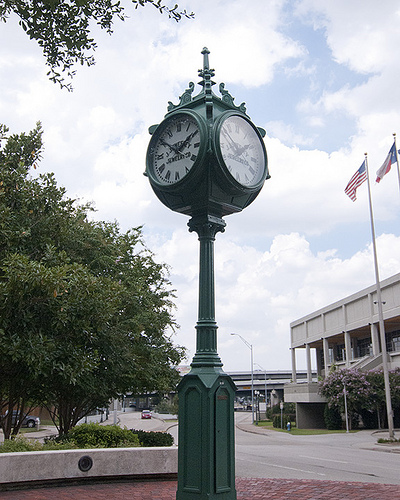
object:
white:
[170, 161, 183, 170]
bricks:
[2, 474, 396, 500]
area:
[0, 271, 398, 498]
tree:
[316, 361, 400, 431]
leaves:
[316, 363, 374, 413]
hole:
[78, 454, 95, 476]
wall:
[0, 451, 177, 487]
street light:
[228, 332, 255, 425]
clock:
[146, 108, 269, 194]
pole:
[175, 215, 239, 500]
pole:
[392, 132, 400, 186]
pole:
[363, 150, 397, 439]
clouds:
[0, 3, 399, 371]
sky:
[0, 7, 397, 369]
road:
[18, 394, 400, 500]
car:
[4, 409, 36, 428]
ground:
[5, 404, 399, 499]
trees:
[2, 123, 182, 432]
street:
[0, 392, 399, 499]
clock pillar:
[173, 214, 238, 500]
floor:
[0, 474, 397, 498]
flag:
[375, 144, 398, 184]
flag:
[344, 160, 368, 202]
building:
[283, 270, 400, 428]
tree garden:
[2, 121, 192, 450]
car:
[141, 410, 152, 419]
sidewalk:
[1, 476, 398, 498]